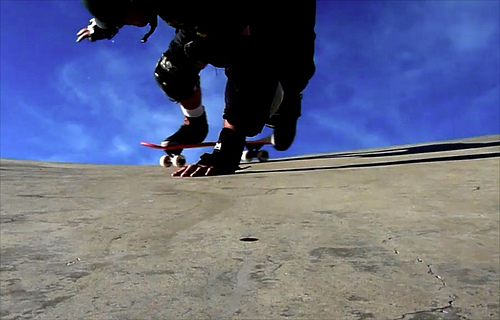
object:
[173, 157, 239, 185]
hand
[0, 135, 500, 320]
ground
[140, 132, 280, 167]
skateboard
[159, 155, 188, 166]
2 wheels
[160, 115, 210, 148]
foot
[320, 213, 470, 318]
crack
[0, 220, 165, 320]
crack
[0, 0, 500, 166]
blue sky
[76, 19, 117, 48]
hand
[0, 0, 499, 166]
air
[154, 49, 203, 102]
knee pad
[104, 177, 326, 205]
pebbles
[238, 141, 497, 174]
shadow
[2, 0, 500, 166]
clouds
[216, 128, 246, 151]
wrist guard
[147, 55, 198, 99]
knee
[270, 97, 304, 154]
foot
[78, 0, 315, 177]
person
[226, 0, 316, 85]
black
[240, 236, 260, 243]
spot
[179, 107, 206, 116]
white socks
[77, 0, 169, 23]
helmet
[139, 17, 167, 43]
chin strap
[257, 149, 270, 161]
back wheels